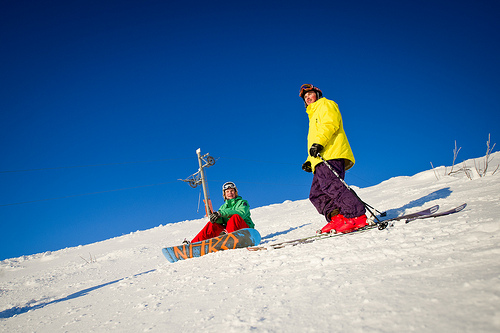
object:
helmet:
[222, 180, 239, 200]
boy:
[182, 182, 255, 243]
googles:
[221, 182, 236, 189]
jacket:
[218, 197, 253, 228]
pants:
[192, 215, 249, 244]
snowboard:
[163, 228, 261, 263]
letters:
[173, 234, 239, 259]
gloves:
[209, 209, 221, 221]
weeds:
[79, 250, 97, 265]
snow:
[0, 151, 498, 332]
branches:
[480, 132, 497, 175]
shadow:
[375, 186, 453, 219]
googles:
[299, 84, 313, 100]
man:
[299, 84, 367, 234]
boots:
[340, 214, 367, 233]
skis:
[250, 202, 467, 252]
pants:
[309, 159, 366, 223]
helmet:
[300, 84, 321, 101]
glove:
[308, 144, 320, 157]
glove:
[301, 158, 312, 172]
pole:
[316, 153, 380, 223]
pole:
[365, 202, 387, 219]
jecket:
[305, 98, 355, 170]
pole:
[193, 147, 213, 217]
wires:
[1, 180, 177, 207]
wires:
[219, 157, 302, 168]